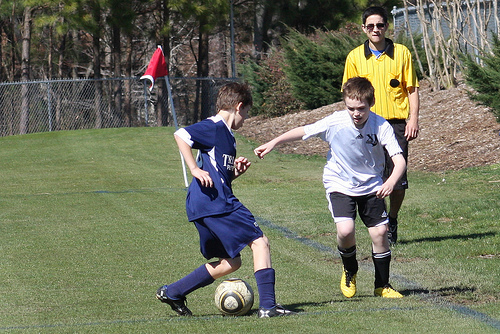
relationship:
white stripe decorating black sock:
[368, 245, 392, 259] [375, 248, 392, 288]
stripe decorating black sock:
[337, 248, 357, 258] [333, 242, 361, 276]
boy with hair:
[252, 67, 426, 303] [337, 68, 379, 102]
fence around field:
[12, 77, 119, 138] [0, 118, 165, 293]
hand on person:
[230, 155, 256, 176] [154, 78, 305, 321]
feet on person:
[164, 252, 329, 331] [149, 73, 301, 330]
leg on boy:
[366, 219, 393, 257] [252, 74, 404, 300]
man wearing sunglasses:
[338, 4, 421, 246] [362, 20, 385, 31]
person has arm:
[161, 57, 299, 332] [171, 117, 216, 177]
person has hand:
[154, 78, 305, 321] [234, 154, 254, 178]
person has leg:
[154, 78, 305, 321] [245, 222, 278, 299]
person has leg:
[154, 78, 305, 321] [170, 248, 242, 294]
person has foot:
[154, 78, 305, 321] [336, 266, 358, 299]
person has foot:
[154, 78, 305, 321] [372, 281, 402, 301]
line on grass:
[254, 213, 499, 330] [2, 125, 498, 330]